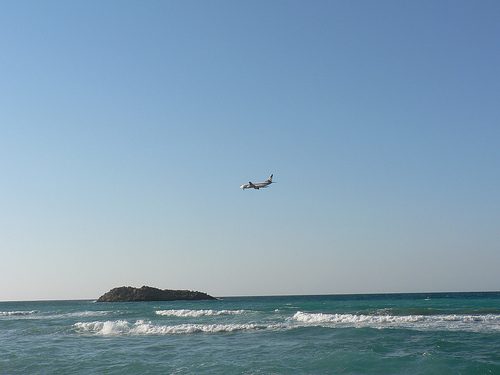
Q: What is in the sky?
A: Plane.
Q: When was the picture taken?
A: Daytime.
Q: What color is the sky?
A: Blue.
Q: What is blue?
A: Ocean.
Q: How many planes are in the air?
A: One.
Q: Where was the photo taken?
A: At the beach.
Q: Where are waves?
A: In the ocean.